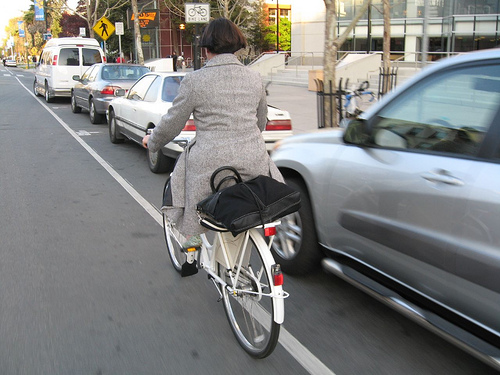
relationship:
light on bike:
[101, 85, 122, 96] [328, 79, 366, 123]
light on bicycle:
[272, 273, 285, 284] [143, 124, 291, 359]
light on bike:
[101, 85, 122, 96] [162, 142, 287, 357]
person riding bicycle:
[140, 18, 283, 277] [143, 124, 291, 359]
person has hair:
[140, 18, 283, 277] [199, 16, 247, 55]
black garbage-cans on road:
[310, 71, 353, 136] [3, 63, 494, 372]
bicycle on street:
[143, 124, 291, 359] [3, 61, 499, 372]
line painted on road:
[8, 64, 341, 374] [3, 63, 494, 372]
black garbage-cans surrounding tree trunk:
[310, 71, 353, 136] [313, 0, 365, 127]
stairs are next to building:
[280, 55, 348, 106] [319, 0, 499, 127]